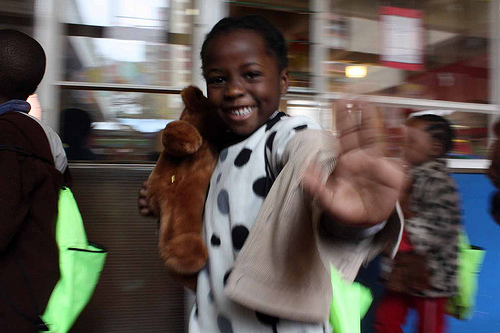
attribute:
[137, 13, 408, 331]
child — African-American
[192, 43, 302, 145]
child — small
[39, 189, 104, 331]
backpack — neon green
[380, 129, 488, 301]
coat — animal print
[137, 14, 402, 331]
she — smiling